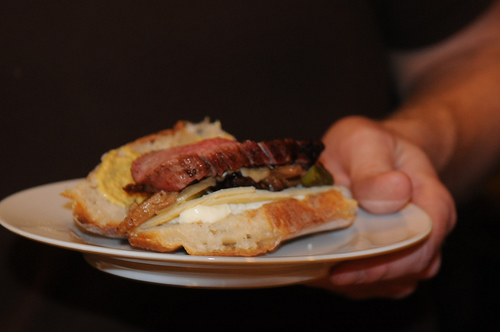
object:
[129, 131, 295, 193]
meat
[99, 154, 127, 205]
cheese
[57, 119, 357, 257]
sandwhich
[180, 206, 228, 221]
mayonnaise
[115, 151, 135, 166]
mustard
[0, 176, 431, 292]
plate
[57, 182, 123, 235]
bread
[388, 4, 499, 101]
shirt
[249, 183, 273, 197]
egg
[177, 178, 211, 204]
onions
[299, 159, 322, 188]
pickles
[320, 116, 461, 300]
hand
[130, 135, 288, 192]
hot dog